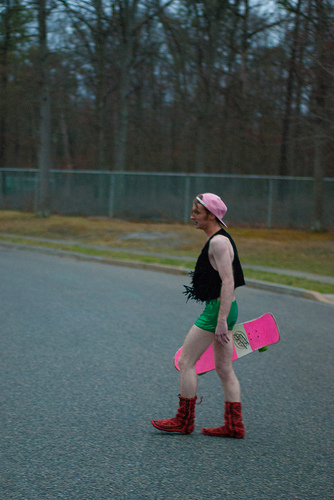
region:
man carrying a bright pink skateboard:
[170, 293, 293, 384]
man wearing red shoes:
[121, 390, 290, 447]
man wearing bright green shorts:
[201, 297, 228, 352]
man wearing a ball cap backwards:
[157, 190, 250, 236]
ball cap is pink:
[185, 185, 248, 237]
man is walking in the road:
[79, 199, 280, 498]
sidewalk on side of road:
[0, 212, 186, 269]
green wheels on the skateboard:
[189, 343, 287, 380]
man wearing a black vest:
[170, 231, 254, 313]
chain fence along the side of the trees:
[2, 153, 321, 232]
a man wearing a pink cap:
[184, 186, 231, 227]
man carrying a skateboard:
[151, 183, 264, 447]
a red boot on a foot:
[145, 388, 211, 445]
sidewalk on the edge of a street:
[88, 226, 142, 274]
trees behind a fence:
[25, 5, 138, 224]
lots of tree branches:
[83, 6, 260, 91]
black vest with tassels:
[171, 223, 250, 305]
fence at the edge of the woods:
[25, 166, 196, 222]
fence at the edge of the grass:
[25, 184, 155, 243]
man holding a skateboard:
[145, 177, 255, 454]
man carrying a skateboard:
[114, 185, 287, 449]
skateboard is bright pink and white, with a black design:
[173, 313, 284, 375]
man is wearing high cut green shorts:
[185, 294, 236, 349]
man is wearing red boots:
[142, 373, 258, 440]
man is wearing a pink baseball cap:
[184, 181, 231, 227]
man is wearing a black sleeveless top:
[170, 222, 264, 304]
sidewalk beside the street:
[7, 232, 274, 270]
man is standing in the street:
[15, 287, 330, 494]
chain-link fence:
[0, 167, 332, 235]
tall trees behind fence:
[2, 1, 327, 220]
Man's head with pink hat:
[173, 178, 238, 231]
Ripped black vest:
[163, 215, 253, 299]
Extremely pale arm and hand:
[208, 236, 236, 339]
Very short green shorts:
[188, 298, 240, 349]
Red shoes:
[139, 391, 256, 443]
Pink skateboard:
[142, 311, 299, 374]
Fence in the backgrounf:
[2, 152, 333, 231]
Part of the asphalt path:
[18, 280, 156, 362]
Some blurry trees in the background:
[15, 9, 329, 145]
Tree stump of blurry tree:
[32, 199, 57, 220]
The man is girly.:
[137, 188, 277, 444]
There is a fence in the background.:
[27, 154, 331, 227]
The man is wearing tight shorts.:
[193, 292, 249, 333]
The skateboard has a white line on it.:
[169, 313, 294, 373]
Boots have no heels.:
[125, 388, 259, 454]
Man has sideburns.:
[189, 191, 219, 228]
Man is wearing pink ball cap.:
[190, 190, 230, 229]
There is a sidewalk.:
[253, 244, 331, 307]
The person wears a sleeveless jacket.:
[194, 231, 267, 314]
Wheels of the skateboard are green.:
[253, 332, 275, 358]